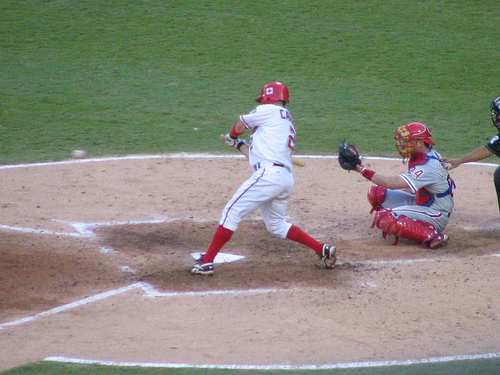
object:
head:
[391, 122, 439, 161]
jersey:
[370, 159, 455, 214]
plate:
[193, 249, 242, 267]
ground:
[1, 0, 498, 373]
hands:
[219, 130, 243, 149]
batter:
[186, 80, 335, 203]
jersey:
[242, 103, 297, 172]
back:
[423, 150, 461, 224]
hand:
[338, 140, 360, 172]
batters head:
[259, 77, 291, 104]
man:
[187, 73, 344, 278]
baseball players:
[176, 59, 459, 283]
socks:
[193, 210, 324, 263]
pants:
[215, 167, 292, 240]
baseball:
[69, 144, 86, 159]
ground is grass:
[3, 5, 500, 83]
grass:
[3, 3, 493, 167]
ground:
[3, 168, 486, 350]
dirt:
[11, 168, 490, 355]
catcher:
[333, 105, 466, 269]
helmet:
[397, 116, 439, 144]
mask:
[392, 125, 416, 158]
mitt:
[330, 136, 360, 169]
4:
[411, 169, 426, 180]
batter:
[195, 74, 338, 274]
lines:
[149, 265, 373, 307]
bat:
[219, 132, 310, 172]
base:
[191, 242, 244, 275]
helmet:
[257, 79, 293, 100]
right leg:
[189, 209, 273, 271]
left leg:
[270, 200, 339, 265]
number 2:
[411, 159, 418, 174]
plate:
[189, 245, 254, 273]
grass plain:
[5, 4, 495, 72]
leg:
[270, 211, 347, 257]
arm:
[333, 151, 419, 196]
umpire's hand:
[439, 136, 492, 184]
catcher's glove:
[333, 135, 360, 174]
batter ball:
[67, 138, 88, 164]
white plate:
[186, 242, 251, 271]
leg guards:
[362, 186, 445, 249]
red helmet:
[253, 81, 290, 103]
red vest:
[400, 154, 439, 207]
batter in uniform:
[191, 77, 341, 277]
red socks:
[204, 224, 319, 256]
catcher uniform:
[329, 114, 470, 255]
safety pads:
[372, 209, 452, 245]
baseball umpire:
[454, 82, 499, 197]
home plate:
[193, 245, 293, 269]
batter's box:
[78, 211, 364, 309]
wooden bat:
[212, 134, 309, 173]